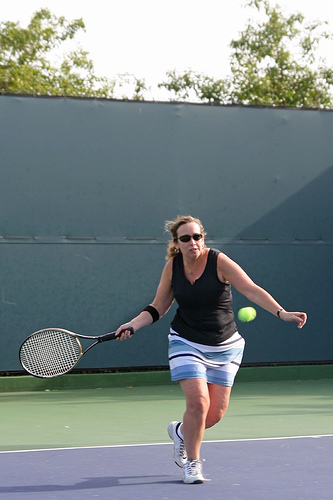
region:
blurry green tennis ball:
[234, 301, 261, 327]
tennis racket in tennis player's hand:
[3, 320, 141, 384]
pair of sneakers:
[161, 417, 213, 487]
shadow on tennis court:
[2, 457, 183, 498]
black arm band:
[137, 302, 164, 323]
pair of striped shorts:
[161, 323, 251, 397]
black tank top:
[158, 248, 247, 346]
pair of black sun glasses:
[169, 232, 208, 246]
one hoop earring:
[169, 245, 182, 255]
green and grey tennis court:
[2, 369, 326, 498]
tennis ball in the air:
[230, 293, 260, 326]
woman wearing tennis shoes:
[177, 447, 207, 486]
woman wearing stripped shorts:
[168, 322, 253, 391]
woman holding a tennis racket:
[4, 293, 152, 387]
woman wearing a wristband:
[135, 301, 164, 333]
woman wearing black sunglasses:
[172, 229, 205, 242]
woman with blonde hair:
[157, 206, 205, 262]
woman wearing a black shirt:
[167, 255, 253, 348]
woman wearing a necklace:
[181, 263, 203, 285]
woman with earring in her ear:
[174, 244, 182, 254]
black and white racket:
[14, 317, 144, 385]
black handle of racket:
[98, 329, 137, 342]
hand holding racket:
[98, 314, 143, 346]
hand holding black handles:
[100, 324, 139, 347]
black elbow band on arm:
[136, 301, 171, 322]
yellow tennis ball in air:
[239, 306, 255, 321]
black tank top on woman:
[172, 245, 242, 346]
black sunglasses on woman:
[176, 225, 204, 244]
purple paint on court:
[18, 456, 38, 474]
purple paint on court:
[52, 457, 63, 476]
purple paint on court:
[85, 454, 106, 470]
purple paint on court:
[121, 458, 139, 478]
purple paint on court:
[151, 459, 164, 479]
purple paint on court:
[216, 455, 245, 487]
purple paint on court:
[258, 456, 281, 476]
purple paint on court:
[296, 439, 323, 470]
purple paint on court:
[293, 470, 315, 496]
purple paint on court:
[139, 479, 166, 498]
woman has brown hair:
[163, 215, 207, 252]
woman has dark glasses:
[170, 228, 201, 244]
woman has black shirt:
[135, 246, 240, 347]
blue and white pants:
[158, 338, 250, 379]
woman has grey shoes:
[151, 415, 200, 487]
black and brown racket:
[25, 312, 82, 390]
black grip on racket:
[54, 317, 135, 346]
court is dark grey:
[102, 438, 231, 491]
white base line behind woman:
[1, 434, 141, 472]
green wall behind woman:
[17, 154, 164, 369]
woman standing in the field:
[140, 209, 246, 434]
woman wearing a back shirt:
[158, 223, 235, 333]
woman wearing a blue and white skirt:
[165, 223, 242, 384]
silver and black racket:
[17, 325, 96, 379]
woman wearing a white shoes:
[171, 424, 203, 483]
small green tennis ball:
[241, 303, 256, 326]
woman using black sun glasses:
[164, 222, 207, 266]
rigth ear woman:
[165, 231, 182, 257]